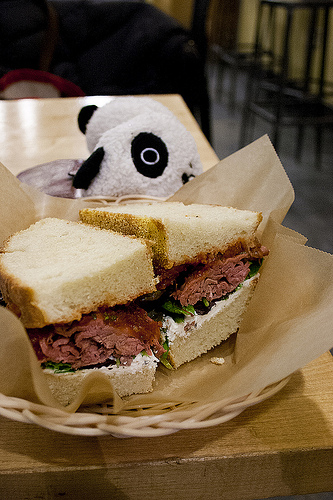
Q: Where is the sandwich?
A: In a basket.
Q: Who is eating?
A: There is no one in the photo.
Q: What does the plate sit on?
A: A table.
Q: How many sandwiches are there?
A: One.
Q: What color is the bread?
A: White.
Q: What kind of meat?
A: Salami.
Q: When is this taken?
A: During a meal.